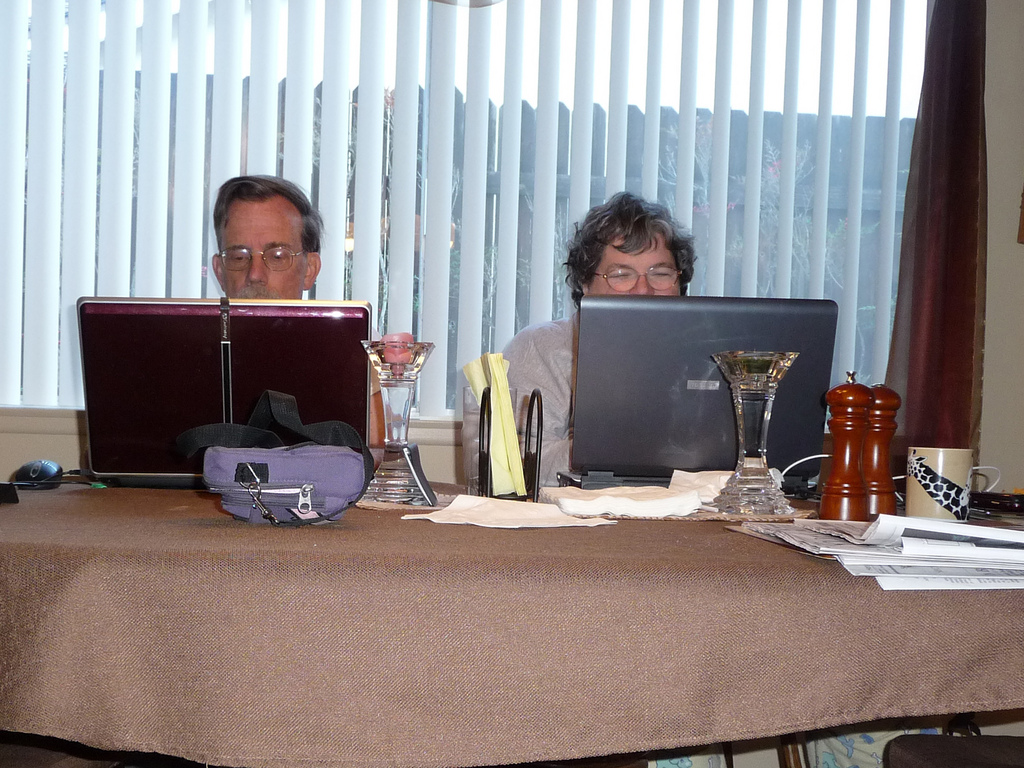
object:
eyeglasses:
[594, 261, 680, 292]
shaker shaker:
[820, 370, 903, 522]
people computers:
[74, 176, 839, 501]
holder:
[476, 386, 543, 504]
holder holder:
[361, 340, 803, 516]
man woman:
[210, 156, 696, 490]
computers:
[75, 294, 838, 500]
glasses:
[214, 245, 682, 291]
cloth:
[0, 481, 1024, 768]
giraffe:
[907, 449, 973, 521]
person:
[502, 192, 700, 484]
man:
[213, 172, 385, 471]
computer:
[557, 296, 837, 500]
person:
[211, 176, 322, 302]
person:
[564, 191, 698, 310]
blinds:
[0, 0, 937, 437]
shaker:
[821, 370, 876, 521]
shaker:
[861, 383, 904, 516]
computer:
[78, 295, 374, 489]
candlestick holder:
[359, 341, 438, 508]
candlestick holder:
[713, 351, 796, 516]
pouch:
[176, 391, 377, 527]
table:
[0, 483, 1023, 768]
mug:
[903, 446, 1000, 524]